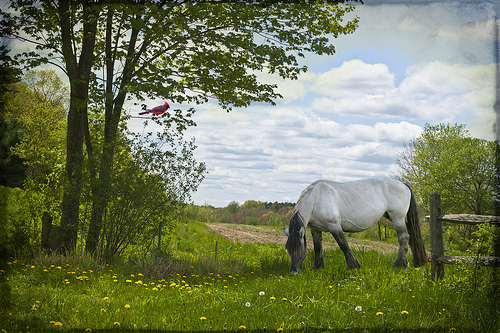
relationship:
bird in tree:
[139, 101, 173, 115] [86, 1, 361, 263]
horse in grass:
[282, 175, 427, 275] [1, 217, 499, 331]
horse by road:
[282, 175, 427, 275] [206, 222, 398, 254]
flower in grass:
[198, 312, 207, 320] [1, 217, 499, 331]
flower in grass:
[53, 319, 62, 326] [1, 217, 499, 331]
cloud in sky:
[306, 58, 397, 95] [1, 1, 499, 202]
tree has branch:
[86, 1, 361, 263] [117, 113, 168, 121]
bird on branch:
[139, 101, 173, 115] [117, 113, 168, 121]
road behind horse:
[206, 222, 398, 254] [282, 175, 427, 275]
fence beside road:
[422, 189, 500, 283] [206, 222, 398, 254]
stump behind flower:
[36, 210, 63, 252] [53, 319, 62, 326]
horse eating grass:
[282, 175, 427, 275] [1, 217, 499, 331]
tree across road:
[449, 133, 497, 239] [206, 222, 398, 254]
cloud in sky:
[308, 95, 444, 119] [1, 1, 499, 202]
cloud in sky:
[211, 158, 278, 171] [1, 1, 499, 202]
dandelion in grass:
[257, 289, 266, 298] [1, 217, 499, 331]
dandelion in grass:
[269, 295, 276, 301] [1, 217, 499, 331]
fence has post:
[422, 189, 500, 283] [427, 191, 446, 280]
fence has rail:
[422, 189, 500, 283] [424, 212, 499, 225]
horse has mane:
[282, 175, 427, 275] [287, 212, 301, 250]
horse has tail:
[282, 175, 427, 275] [406, 180, 428, 266]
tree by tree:
[86, 1, 361, 263] [2, 1, 105, 250]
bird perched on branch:
[139, 101, 173, 115] [117, 113, 168, 121]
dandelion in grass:
[124, 277, 133, 283] [1, 217, 499, 331]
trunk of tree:
[84, 85, 124, 258] [86, 1, 361, 263]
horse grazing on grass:
[282, 175, 427, 275] [1, 217, 499, 331]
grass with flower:
[1, 217, 499, 331] [400, 307, 409, 316]